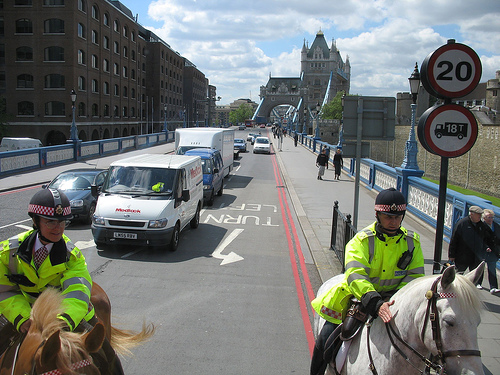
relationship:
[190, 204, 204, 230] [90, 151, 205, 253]
tire of van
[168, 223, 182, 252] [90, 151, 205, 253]
tire of van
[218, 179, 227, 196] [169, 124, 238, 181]
tire of van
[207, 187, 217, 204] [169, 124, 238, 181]
tire of van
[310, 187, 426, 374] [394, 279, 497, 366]
cop on a horse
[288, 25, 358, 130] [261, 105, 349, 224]
structure next to bridge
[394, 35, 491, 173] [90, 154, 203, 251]
sign for van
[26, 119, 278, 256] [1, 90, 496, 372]
traffic on bridge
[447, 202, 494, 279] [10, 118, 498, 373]
people walking on bridge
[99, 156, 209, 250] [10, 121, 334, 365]
van driving down street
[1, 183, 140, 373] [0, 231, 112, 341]
officer wearing coat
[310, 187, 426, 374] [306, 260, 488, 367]
cop on horses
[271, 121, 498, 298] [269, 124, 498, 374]
pedestrians walking on sidewalk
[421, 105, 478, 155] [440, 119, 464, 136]
sign on 18t truck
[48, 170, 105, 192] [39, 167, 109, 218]
window on car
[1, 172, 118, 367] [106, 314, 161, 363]
horse has tail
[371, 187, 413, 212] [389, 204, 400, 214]
helmet with badge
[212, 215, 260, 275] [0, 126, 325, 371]
arrow on lane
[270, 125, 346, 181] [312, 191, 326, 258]
people walking down sidewalk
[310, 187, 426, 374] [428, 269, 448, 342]
cop riding horse